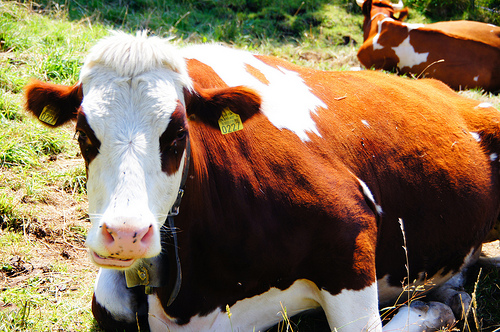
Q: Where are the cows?
A: On grass.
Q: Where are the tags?
A: Cow's ears.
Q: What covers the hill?
A: Grass.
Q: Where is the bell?
A: Around cow's neck.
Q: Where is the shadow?
A: On grass.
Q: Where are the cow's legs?
A: Under it.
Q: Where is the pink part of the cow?
A: Nose.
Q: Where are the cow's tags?
A: Ears.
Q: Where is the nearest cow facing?
A: The camera.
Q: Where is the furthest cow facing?
A: Away from camera.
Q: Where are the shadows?
A: On grass.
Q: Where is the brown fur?
A: On cows.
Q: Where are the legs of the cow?
A: Under the cows.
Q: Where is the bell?
A: Around the cow's neck.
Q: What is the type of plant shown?
A: Grass.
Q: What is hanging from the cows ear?
A: Tags.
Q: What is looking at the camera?
A: Cow.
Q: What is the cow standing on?
A: Grass.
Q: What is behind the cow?
A: Grass.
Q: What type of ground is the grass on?
A: Small hill.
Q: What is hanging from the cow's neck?
A: Bell.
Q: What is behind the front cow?
A: Another cow.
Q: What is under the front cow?
A: Stone.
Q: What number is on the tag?
A: 0227.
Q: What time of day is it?
A: Afternoon.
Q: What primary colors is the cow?
A: Brown and white.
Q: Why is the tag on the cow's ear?
A: Identification.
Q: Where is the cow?
A: Field.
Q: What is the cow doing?
A: Sitting.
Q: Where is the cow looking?
A: At camera.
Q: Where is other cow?
A: Behind first one.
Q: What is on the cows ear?
A: A tag.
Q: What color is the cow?
A: Brown and white.